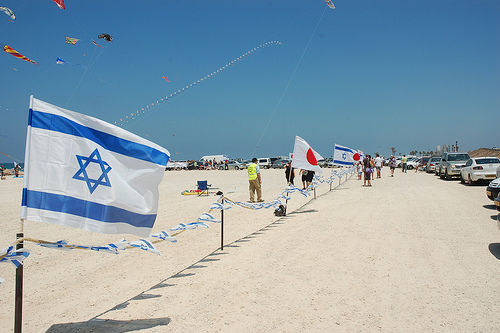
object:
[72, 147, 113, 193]
star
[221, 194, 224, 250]
post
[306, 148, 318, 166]
circle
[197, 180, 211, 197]
chair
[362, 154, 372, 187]
man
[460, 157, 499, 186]
car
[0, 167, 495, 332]
beach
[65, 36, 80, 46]
kite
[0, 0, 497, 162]
sky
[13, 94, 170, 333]
flag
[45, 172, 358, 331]
shadow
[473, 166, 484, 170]
tail light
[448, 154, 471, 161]
windshield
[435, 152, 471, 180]
car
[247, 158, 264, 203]
man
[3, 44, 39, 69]
kites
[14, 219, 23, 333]
pole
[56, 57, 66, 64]
kite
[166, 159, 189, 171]
car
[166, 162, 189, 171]
suv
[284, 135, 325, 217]
flag